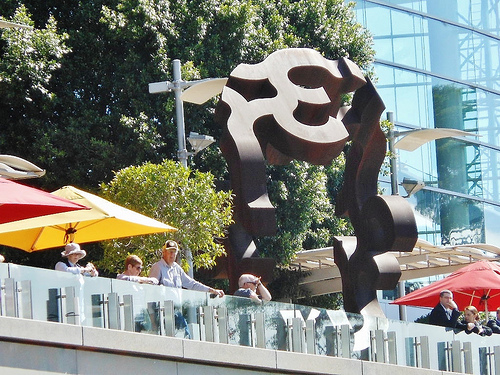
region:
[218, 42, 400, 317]
Brown modern metal sculpture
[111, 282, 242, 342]
Glass panels in front of people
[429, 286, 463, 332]
Man in a suit with his right hand on his face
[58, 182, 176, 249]
Open yellow umbrella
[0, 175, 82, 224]
Red umbrella next to a yellow umbrella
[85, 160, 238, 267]
Leaves on a tree behind people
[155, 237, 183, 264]
Face of man wearing ball cap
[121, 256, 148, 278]
Woman wearing sunglasses looking down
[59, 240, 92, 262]
Woman wearing sun hat looking forward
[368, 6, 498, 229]
Glass windows of a building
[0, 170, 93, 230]
corner of a red umbrella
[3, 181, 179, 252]
large yellow open umbrella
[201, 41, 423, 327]
sculpture in a plaza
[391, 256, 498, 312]
large open red umbrella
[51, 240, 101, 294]
woman wearing a hat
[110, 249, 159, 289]
woman with red hair and sun glasses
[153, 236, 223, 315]
tall man wearing a hat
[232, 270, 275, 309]
white haired man wearing sun glasses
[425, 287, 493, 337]
two people against rail on right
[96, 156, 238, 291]
small tree with green leaves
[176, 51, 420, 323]
a statue in front of the trees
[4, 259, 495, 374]
the wall at the end of the path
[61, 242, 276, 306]
people standing around looking at stuff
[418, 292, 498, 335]
more people standing around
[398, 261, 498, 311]
a red umbrella behind the people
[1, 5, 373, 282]
some trees next to the buildings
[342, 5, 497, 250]
a building made of glass next to the trees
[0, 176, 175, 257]
two umbrellas standing next to each other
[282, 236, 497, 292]
a canopy cover in front of the building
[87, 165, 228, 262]
a bright green tree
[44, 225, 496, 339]
People stand in a bridge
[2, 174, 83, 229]
Umbrella is red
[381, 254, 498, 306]
Canopy of umbrella is red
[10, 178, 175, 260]
Yellow umbrella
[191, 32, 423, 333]
Sculpture on the street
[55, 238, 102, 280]
Woman has a hat on head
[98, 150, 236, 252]
Bush behind people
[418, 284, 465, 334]
Man wears black jacket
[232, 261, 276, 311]
Woman wears sunglasses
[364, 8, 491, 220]
Building with glass windows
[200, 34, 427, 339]
large black sculpture.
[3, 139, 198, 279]
yellow umbrella near sculpture.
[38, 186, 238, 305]
people standing on an upper level.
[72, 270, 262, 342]
wall near the edge.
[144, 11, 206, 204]
tall light pole near sculpture.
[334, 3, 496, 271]
Tall building with lots of windows.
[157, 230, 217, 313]
Man holding his hand on ledge.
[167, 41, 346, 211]
section of an odd black sculpture.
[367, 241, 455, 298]
wooden covering.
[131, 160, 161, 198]
section of small tree with lots of leaves.